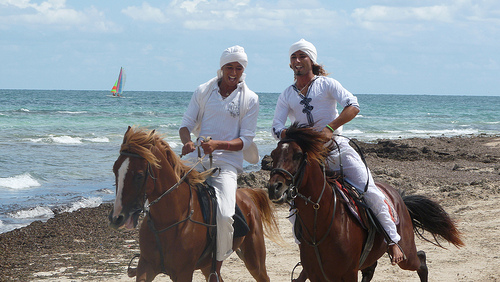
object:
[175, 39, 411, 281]
riders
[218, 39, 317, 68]
turbans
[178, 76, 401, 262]
outfits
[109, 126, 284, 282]
horse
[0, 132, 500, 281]
beach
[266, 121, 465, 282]
horse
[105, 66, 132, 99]
sailboat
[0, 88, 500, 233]
ocean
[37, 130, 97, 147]
waves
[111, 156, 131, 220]
white stripe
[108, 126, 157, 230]
horses head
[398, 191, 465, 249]
tail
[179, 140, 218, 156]
hands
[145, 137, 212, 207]
reins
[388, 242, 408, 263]
foot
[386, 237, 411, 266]
stirrup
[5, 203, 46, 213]
seaweed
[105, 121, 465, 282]
horses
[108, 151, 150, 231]
face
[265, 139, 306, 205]
dark face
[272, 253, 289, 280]
sand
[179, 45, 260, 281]
man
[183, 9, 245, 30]
clouds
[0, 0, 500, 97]
sky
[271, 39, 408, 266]
man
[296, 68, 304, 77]
facial hair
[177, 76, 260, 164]
clothes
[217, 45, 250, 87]
head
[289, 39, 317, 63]
turban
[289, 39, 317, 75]
head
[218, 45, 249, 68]
turban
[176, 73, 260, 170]
shirt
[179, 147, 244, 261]
pants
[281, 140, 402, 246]
pants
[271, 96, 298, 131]
white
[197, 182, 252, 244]
saddle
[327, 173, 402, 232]
saddle